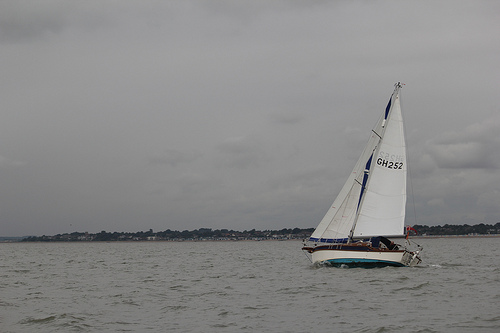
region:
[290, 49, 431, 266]
the sailboat is sailing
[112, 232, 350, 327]
the water is moving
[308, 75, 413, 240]
the sail is white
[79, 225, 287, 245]
houses on the shore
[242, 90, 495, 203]
the sky is cloudy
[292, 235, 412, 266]
the boat is made of wood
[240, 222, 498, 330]
the water is choppy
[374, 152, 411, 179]
writing in black on the sail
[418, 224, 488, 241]
a beach in the distance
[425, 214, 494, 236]
trees all in a row in the background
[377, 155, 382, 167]
The letter G on the sail of the boat.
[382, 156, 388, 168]
The letter H on the sail of the boat.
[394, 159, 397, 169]
The number 5 on the sail boat.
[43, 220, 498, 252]
The buildings in the distance.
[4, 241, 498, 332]
The water the sail boat is sailing on.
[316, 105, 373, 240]
The left side of the sail.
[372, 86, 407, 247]
The right side of the sail.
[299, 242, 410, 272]
The boat area of the sail boat.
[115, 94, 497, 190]
The clouds in the sky.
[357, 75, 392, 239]
The blue strip on the sail of the boat.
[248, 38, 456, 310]
a sailboat on water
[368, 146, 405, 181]
the registry is gh252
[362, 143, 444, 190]
the font is black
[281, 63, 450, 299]
the registry is on the sail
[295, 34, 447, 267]
the bottom hull is blue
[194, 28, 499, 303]
the sky is overcast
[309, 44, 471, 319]
there are two sails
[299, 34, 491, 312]
the boat is turning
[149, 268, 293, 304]
the water is grey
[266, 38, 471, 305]
the sails are white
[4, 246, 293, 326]
A gentle water mass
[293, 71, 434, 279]
A sail boat in the water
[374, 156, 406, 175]
A sail boat's identifier tag on the sails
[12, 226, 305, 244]
A land mass with buildings in the background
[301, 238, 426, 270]
The body of the sail boat keeling on the side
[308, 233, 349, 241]
Deep blue markings on the sails of the boat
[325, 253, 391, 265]
Sky blue painting on the under side of the boat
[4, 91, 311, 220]
The sky, laden with heavy cloud cover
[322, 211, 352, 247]
Harnesting ropes in the foreground of the sail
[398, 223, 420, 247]
A red piece of ribon on the back of the sail boat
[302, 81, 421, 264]
sail boat in lake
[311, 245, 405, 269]
white and blue boat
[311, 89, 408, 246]
white and blue sail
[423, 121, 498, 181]
storm clouds in sky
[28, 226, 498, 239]
trees next to lake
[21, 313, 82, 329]
ripple on lake surface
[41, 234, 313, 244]
houses next to lake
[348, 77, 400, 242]
white metal pole on boat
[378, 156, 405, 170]
black letters on sale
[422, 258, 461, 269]
white cap made by boat